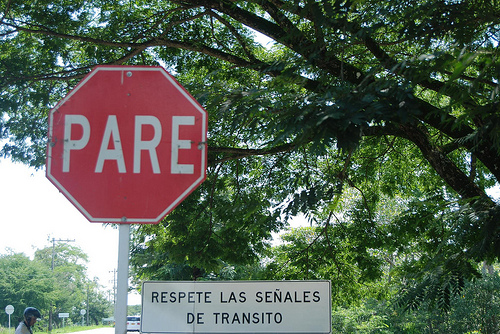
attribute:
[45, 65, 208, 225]
sign — red, white, octagonal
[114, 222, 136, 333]
pole — white, metal, grey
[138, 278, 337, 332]
sign — white, black, rectangular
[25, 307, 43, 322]
helmet — dark, black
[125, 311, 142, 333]
car — white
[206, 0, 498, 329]
tree — green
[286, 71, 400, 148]
leaves — green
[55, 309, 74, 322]
sign — present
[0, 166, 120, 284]
sky — white, bright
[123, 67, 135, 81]
bolt — silver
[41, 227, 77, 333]
pole — wooden, brown, Tall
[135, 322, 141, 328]
lights — red